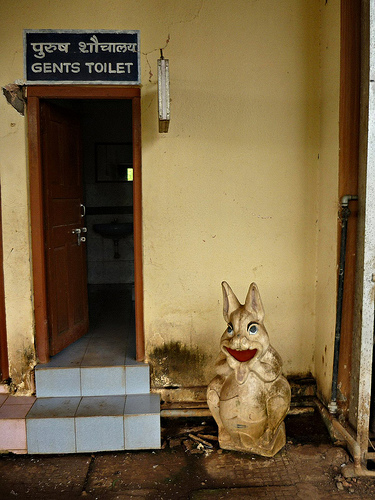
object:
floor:
[0, 399, 375, 498]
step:
[0, 390, 35, 457]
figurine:
[206, 279, 297, 458]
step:
[24, 393, 161, 453]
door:
[27, 86, 144, 361]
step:
[34, 360, 151, 399]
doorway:
[23, 88, 143, 370]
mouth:
[220, 341, 262, 366]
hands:
[248, 358, 259, 370]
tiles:
[74, 414, 126, 454]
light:
[157, 48, 171, 133]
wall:
[0, 0, 341, 399]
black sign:
[21, 27, 142, 85]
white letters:
[31, 61, 43, 73]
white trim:
[14, 28, 140, 85]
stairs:
[25, 391, 161, 456]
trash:
[194, 439, 210, 450]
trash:
[145, 461, 164, 474]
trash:
[161, 420, 215, 455]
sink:
[93, 220, 132, 261]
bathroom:
[0, 0, 314, 412]